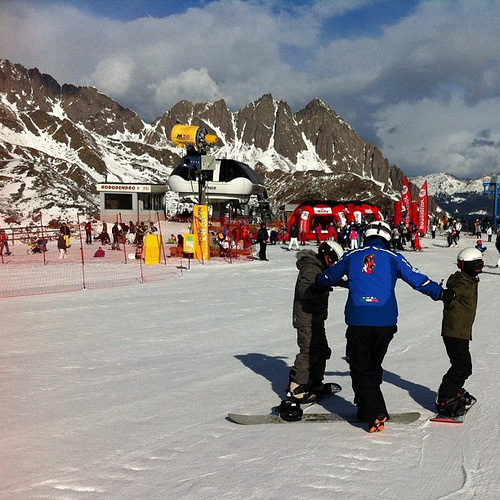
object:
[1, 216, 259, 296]
fencing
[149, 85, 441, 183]
rocks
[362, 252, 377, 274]
logo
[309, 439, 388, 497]
tracks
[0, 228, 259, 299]
net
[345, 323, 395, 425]
pants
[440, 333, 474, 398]
pants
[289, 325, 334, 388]
pants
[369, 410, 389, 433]
shoes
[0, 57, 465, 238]
mountain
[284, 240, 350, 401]
man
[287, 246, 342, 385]
suit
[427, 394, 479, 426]
snowboard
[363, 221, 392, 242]
helmet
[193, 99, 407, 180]
rocks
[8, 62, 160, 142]
rocks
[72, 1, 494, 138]
sky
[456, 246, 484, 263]
helmets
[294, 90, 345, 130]
mountain top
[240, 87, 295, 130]
mountain top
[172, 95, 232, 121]
mountain top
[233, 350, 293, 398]
shadow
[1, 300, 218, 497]
snow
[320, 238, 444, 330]
coat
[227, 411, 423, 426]
boards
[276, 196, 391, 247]
tent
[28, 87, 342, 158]
rocks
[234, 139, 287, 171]
snow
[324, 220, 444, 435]
man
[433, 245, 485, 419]
man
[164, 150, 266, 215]
ski lift